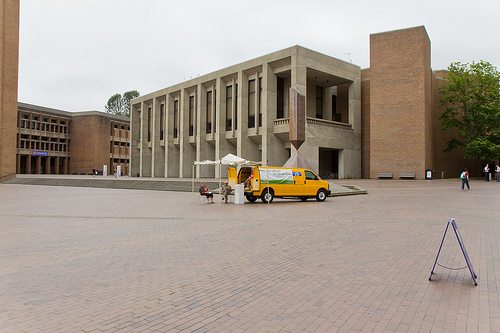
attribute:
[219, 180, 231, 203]
man — wearing all gray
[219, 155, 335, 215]
van — yellow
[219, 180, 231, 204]
person — behind, sitting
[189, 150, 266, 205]
canopy — covering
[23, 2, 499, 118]
sky — white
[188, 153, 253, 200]
tent — white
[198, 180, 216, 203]
person — under, sitting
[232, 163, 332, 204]
van — yellow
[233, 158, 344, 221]
van — yellow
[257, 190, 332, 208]
tires — black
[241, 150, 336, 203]
van — yellow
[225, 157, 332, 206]
yellow van — large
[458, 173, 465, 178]
backpack — blue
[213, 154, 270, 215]
back doors — open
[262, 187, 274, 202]
wheel — back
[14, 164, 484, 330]
ground — brick